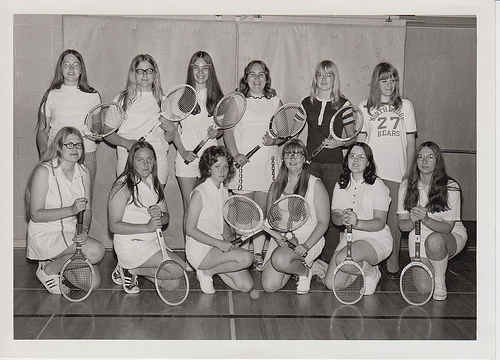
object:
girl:
[106, 138, 187, 295]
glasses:
[134, 67, 155, 75]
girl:
[98, 51, 180, 197]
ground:
[450, 254, 472, 296]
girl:
[186, 147, 263, 294]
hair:
[195, 146, 234, 183]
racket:
[400, 214, 435, 304]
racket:
[329, 208, 365, 305]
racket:
[161, 82, 196, 115]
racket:
[53, 243, 97, 295]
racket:
[142, 207, 191, 305]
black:
[268, 115, 293, 141]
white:
[282, 100, 306, 122]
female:
[107, 141, 184, 293]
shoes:
[33, 252, 146, 303]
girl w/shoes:
[323, 140, 393, 298]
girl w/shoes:
[105, 139, 185, 301]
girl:
[289, 57, 357, 267]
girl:
[393, 142, 459, 297]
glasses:
[61, 60, 83, 69]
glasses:
[417, 153, 437, 160]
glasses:
[348, 153, 367, 160]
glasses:
[318, 71, 333, 78]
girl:
[328, 140, 392, 294]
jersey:
[355, 96, 426, 185]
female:
[395, 139, 468, 305]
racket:
[82, 97, 120, 146]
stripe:
[14, 310, 478, 324]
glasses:
[282, 151, 307, 158]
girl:
[260, 138, 330, 292]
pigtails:
[268, 137, 308, 221]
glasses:
[283, 150, 306, 158]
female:
[184, 146, 256, 293]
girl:
[24, 127, 105, 294]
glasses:
[58, 141, 83, 149]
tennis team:
[25, 47, 467, 304]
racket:
[76, 100, 129, 138]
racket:
[186, 91, 249, 165]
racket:
[234, 103, 306, 170]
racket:
[300, 106, 365, 162]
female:
[331, 139, 394, 297]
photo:
[16, 13, 476, 340]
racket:
[229, 192, 311, 249]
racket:
[220, 195, 305, 262]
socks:
[424, 251, 451, 288]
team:
[63, 64, 396, 303]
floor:
[11, 219, 470, 341]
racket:
[58, 197, 94, 304]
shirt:
[263, 62, 385, 216]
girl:
[36, 48, 100, 179]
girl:
[177, 53, 216, 180]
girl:
[260, 140, 327, 303]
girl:
[298, 57, 357, 178]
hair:
[400, 136, 459, 224]